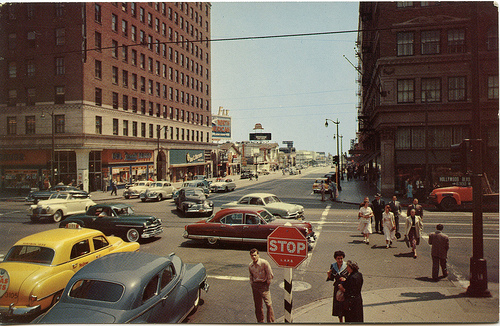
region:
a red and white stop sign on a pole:
[267, 225, 308, 324]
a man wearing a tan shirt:
[247, 248, 276, 322]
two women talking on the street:
[326, 249, 363, 322]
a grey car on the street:
[28, 251, 210, 323]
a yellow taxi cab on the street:
[1, 221, 140, 316]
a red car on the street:
[183, 208, 315, 245]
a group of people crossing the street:
[356, 192, 450, 280]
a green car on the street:
[60, 202, 162, 242]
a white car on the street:
[28, 187, 95, 222]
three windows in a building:
[393, 28, 468, 56]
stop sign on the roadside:
[267, 225, 308, 324]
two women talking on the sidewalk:
[326, 250, 363, 324]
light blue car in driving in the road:
[29, 250, 208, 323]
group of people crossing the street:
[360, 195, 450, 282]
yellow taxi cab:
[2, 223, 140, 315]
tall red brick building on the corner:
[0, 27, 212, 186]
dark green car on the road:
[63, 203, 163, 240]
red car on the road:
[181, 207, 316, 254]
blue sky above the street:
[208, 28, 385, 163]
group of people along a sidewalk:
[248, 163, 451, 324]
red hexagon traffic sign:
[264, 229, 316, 274]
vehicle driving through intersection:
[190, 205, 314, 247]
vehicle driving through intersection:
[74, 203, 162, 240]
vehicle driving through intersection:
[36, 191, 93, 214]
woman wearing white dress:
[359, 199, 379, 239]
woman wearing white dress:
[381, 205, 398, 247]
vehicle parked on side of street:
[306, 171, 333, 193]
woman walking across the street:
[357, 199, 379, 246]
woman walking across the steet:
[381, 202, 401, 252]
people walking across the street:
[348, 183, 429, 257]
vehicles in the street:
[1, 192, 203, 324]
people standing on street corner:
[326, 245, 375, 324]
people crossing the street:
[351, 192, 456, 282]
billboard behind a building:
[210, 105, 233, 140]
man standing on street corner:
[240, 245, 279, 322]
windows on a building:
[395, 75, 466, 102]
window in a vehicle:
[65, 281, 122, 303]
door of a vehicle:
[215, 225, 239, 237]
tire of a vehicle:
[201, 236, 223, 245]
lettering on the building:
[175, 154, 215, 161]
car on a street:
[110, 245, 212, 310]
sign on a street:
[260, 225, 310, 315]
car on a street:
[185, 205, 255, 245]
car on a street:
[106, 195, 166, 235]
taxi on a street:
[5, 223, 66, 281]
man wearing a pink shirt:
[240, 245, 263, 318]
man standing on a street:
[237, 240, 267, 315]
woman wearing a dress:
[315, 245, 343, 320]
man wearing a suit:
[426, 210, 448, 281]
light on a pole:
[313, 112, 358, 181]